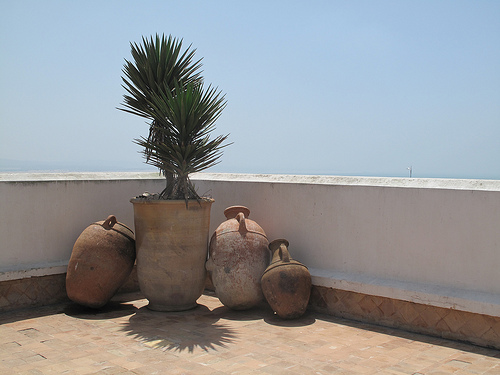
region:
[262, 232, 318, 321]
a small tan pot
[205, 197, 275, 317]
a large light tan pot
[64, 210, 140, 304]
a large tan pot with black marks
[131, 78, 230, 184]
a green plant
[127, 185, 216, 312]
a large pot with a plant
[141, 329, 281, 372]
a shadow on the ground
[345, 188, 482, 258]
a small white wall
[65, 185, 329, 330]
four pots on each other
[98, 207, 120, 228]
a handle on a pot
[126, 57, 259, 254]
Green leaves on plant.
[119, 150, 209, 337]
Plant in large pot.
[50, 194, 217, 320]
Pot leaning against other pot.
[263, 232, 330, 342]
Brown pot sitting on ground.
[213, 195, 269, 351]
Large pot in between two other pots.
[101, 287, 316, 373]
Ground under pots is brick.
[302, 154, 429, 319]
Wall behind pots is white.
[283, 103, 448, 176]
Sky is blue and clear.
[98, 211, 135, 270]
Handle on top of pot.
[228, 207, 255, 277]
Handle on pot is facing forward.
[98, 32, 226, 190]
The plant is green.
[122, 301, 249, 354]
The plant is casting a shadow.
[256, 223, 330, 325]
Small old water jug.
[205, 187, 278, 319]
Larger old water jug.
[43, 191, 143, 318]
An old brown container.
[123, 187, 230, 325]
The pot is made of clay.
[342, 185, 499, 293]
The wall is white.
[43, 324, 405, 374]
The ground is tan.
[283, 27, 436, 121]
The sky is blue.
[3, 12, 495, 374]
Picture was taken on a balcony.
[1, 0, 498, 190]
the bright blue cloudless sky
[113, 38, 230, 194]
the palm tree standing in the corner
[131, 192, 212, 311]
the pot in the corner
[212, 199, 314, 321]
the empty pots next to the bigger pot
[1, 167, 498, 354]
the white and brown wall next to the pots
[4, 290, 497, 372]
the tile floor next to the wall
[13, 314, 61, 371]
some of the tiles are sinking down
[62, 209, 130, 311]
a seperate pot on the left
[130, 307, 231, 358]
the shadow of the pot and plant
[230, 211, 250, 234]
the handle of the pot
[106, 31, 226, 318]
green palm tree in pot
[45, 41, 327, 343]
four clay pots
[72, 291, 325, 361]
four shadows from four clay pots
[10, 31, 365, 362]
deck and sky on sunny day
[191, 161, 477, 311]
ledge of deck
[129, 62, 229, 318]
potted plant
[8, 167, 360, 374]
tile and cement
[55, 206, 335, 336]
three pieces of pottery with handles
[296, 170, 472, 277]
cement painted white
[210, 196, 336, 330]
pottery with handles